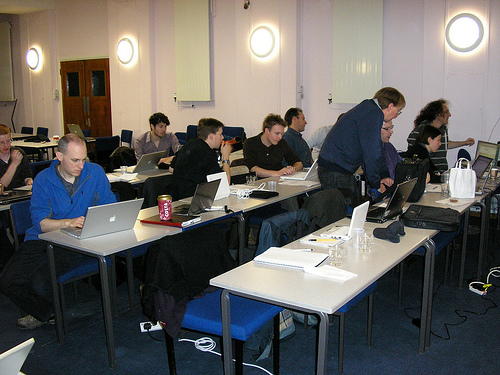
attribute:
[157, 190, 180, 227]
can — red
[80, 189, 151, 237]
laptop — silver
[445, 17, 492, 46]
lamp — bright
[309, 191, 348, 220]
jacket — black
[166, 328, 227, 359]
cord — white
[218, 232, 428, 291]
table — white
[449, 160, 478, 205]
bag — white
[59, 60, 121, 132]
doors — wooden, brown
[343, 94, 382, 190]
sweater — blue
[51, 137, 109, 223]
man — typing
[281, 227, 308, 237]
collar — black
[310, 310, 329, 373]
leg — grey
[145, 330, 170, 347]
wire — black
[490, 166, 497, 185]
cup — gold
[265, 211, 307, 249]
jacket — blue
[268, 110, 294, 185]
man — typing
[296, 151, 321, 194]
laptop — white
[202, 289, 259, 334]
seat — blue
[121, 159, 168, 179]
computer — silver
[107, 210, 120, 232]
logo — apple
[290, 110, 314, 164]
student — working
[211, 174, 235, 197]
laptop — white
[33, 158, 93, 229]
sweater — blue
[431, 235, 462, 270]
chair — blue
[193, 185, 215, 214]
laptop — silver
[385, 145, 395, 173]
sweathirt — blue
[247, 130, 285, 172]
shirt — buttoned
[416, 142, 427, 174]
shirt — black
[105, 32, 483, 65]
lights — round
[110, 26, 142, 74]
light — round